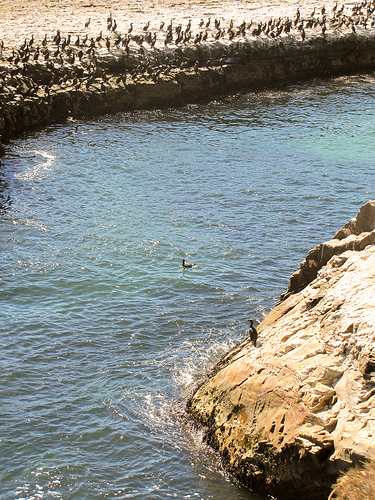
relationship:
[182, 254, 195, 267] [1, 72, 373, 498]
bird floating in water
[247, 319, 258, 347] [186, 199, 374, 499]
bird on rock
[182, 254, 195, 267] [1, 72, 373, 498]
bird on water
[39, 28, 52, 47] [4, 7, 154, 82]
bird on beach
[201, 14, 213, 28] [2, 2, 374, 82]
bird on beach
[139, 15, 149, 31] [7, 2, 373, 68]
bird on beach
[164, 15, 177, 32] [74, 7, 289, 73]
bird on beach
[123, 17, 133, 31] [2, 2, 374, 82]
bird on beach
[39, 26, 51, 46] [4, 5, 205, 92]
bird on beach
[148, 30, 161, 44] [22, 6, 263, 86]
bird on beach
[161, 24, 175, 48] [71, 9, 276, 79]
bird on beach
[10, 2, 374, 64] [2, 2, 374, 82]
birds on beach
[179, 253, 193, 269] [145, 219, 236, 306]
bird in water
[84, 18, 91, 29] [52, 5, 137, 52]
bird in beach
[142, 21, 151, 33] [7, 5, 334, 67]
bird on beach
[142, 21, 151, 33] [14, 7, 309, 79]
bird on beach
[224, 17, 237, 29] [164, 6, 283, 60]
bird on beach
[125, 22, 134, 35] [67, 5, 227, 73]
bird on beach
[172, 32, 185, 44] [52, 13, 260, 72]
bird on beach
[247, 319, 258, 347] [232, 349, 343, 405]
bird on rock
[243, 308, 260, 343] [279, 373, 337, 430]
bird on rock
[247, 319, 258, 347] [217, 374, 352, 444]
bird standing rocks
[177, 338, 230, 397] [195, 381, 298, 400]
splash on rocks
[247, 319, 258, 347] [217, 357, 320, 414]
bird standing rock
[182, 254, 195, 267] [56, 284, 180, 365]
bird swimming water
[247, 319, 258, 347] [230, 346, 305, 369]
bird standing rock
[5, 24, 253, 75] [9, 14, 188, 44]
bird walking grassland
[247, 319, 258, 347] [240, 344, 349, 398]
bird looking rock